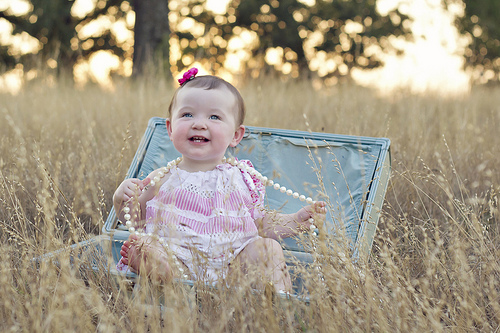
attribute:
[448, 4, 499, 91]
tree — green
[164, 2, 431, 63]
foliage — green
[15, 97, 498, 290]
field — straw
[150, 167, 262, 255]
dress — pink, white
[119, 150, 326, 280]
dress — pink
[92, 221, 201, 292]
toes — beautiful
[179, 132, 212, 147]
smile — nice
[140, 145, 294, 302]
dress — white, pink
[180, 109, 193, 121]
eye — bright, blue, clear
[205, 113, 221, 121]
eye — bright, blue, clear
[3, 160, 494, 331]
yellow straw — tall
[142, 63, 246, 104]
bow — pink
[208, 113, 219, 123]
blue eye — pretty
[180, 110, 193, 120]
blue eye — pretty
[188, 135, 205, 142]
teeth — white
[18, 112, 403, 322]
suitcase — light blue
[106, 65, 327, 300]
baby — cute, smiling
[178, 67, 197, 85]
bow — pink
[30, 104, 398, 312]
blue suitcase — open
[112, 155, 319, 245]
pearl necklace — long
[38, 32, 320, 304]
baby — blue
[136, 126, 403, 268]
suitcase — light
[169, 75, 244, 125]
hair — deep brown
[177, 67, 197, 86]
bow — deep pink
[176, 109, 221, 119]
eyes — blue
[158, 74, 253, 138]
hair — thin, dark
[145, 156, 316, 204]
pearls — white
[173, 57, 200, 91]
hair clip — pink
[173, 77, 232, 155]
face — smiling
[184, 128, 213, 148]
mouth — open, smiling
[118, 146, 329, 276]
necklace — pearl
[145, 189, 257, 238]
pattern — pink, white, striped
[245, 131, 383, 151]
edge — interior, torn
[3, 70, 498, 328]
grass — tall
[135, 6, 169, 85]
bark — brown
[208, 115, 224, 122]
eye — blue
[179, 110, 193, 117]
eye — blue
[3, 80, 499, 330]
field — high, wheat, dry